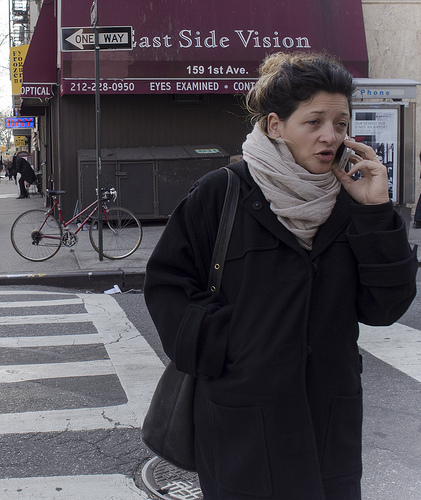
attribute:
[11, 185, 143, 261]
bike — red framed, red, parked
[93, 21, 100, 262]
pole — grey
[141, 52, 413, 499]
woman — speaking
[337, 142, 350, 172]
cell phone — silver colored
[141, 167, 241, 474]
purse — dark colored, black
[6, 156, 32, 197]
man — seated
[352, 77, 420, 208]
phone booth — here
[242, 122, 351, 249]
scarf — thick, beige, white, cream tan color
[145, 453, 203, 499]
man hole cover — round, metal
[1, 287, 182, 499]
pedestrian crossing — marked, painted white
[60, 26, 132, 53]
one way street sign — black, white, pointing left, here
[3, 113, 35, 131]
sign — red, blue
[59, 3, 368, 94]
awning — advertisement, maroon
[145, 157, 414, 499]
coat — black, large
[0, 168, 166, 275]
sidewalk — here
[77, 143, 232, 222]
garbage bin — brown